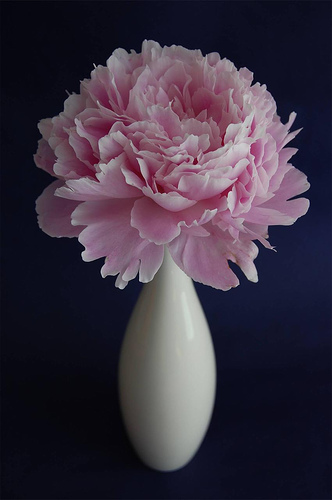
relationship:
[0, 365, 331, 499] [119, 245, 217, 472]
table under jug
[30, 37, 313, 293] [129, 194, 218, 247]
flower has petal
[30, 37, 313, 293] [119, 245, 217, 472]
flower in jug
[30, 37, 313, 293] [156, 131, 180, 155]
flower has center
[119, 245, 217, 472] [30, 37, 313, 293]
jug holds flower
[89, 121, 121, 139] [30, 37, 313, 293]
shadow in flower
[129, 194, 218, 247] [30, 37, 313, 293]
petal on flower